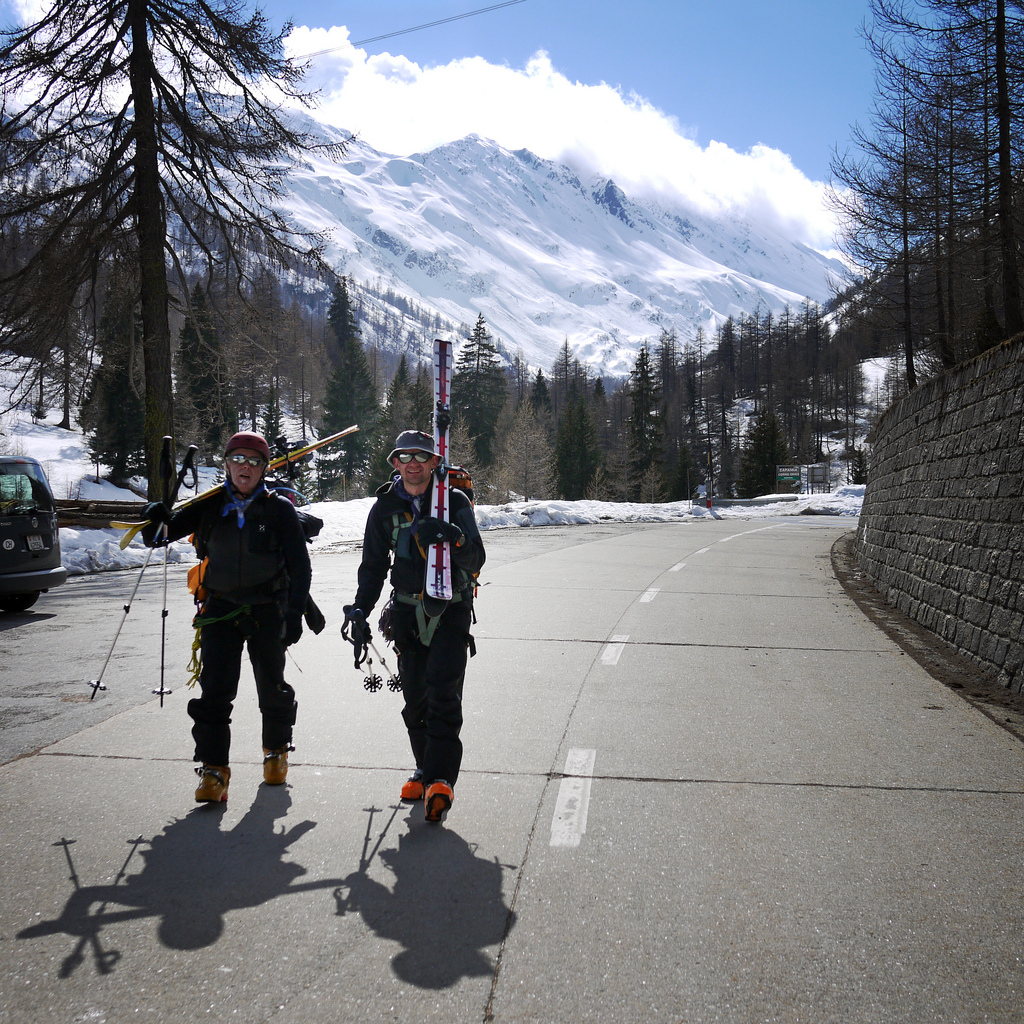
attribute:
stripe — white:
[596, 627, 628, 666]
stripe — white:
[671, 553, 685, 574]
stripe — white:
[716, 520, 797, 543]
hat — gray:
[386, 431, 447, 469]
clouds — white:
[5, 0, 872, 254]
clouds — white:
[1, 0, 883, 285]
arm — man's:
[424, 492, 483, 572]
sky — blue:
[0, 3, 1024, 278]